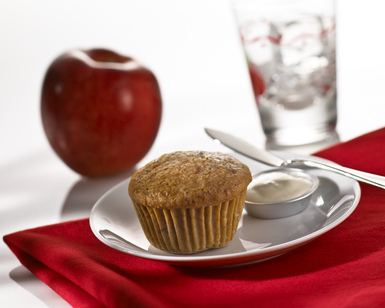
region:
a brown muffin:
[130, 151, 251, 251]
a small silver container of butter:
[246, 166, 318, 219]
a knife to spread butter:
[202, 123, 383, 190]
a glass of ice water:
[234, 3, 342, 148]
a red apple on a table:
[41, 47, 162, 178]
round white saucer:
[86, 153, 362, 263]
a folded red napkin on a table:
[5, 123, 383, 306]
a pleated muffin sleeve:
[130, 190, 253, 255]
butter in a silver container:
[248, 168, 312, 203]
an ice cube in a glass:
[239, 19, 275, 38]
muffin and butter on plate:
[102, 119, 372, 263]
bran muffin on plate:
[142, 161, 246, 250]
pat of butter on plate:
[244, 176, 316, 210]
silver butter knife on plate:
[207, 125, 265, 169]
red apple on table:
[43, 52, 158, 169]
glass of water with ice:
[237, 0, 330, 145]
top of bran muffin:
[146, 153, 225, 203]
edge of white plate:
[146, 247, 170, 266]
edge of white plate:
[235, 243, 263, 267]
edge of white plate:
[294, 227, 315, 246]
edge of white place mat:
[5, 267, 35, 285]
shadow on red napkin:
[198, 267, 249, 286]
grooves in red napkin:
[38, 237, 111, 287]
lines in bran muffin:
[140, 211, 225, 244]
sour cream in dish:
[252, 163, 290, 187]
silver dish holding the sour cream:
[257, 195, 312, 218]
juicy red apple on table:
[41, 49, 153, 148]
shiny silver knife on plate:
[200, 124, 359, 196]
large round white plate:
[74, 158, 353, 277]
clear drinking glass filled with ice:
[221, 3, 343, 148]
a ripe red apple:
[39, 46, 161, 179]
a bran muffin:
[130, 149, 249, 252]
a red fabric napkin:
[4, 124, 384, 306]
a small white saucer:
[91, 141, 359, 265]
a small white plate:
[87, 143, 359, 266]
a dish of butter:
[242, 165, 317, 218]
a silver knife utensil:
[204, 125, 383, 189]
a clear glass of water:
[227, 1, 340, 144]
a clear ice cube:
[239, 18, 276, 64]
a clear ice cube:
[276, 15, 326, 62]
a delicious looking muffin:
[125, 150, 252, 256]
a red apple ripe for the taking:
[39, 45, 165, 182]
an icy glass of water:
[232, 5, 341, 154]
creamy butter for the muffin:
[243, 166, 320, 221]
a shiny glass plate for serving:
[86, 148, 363, 264]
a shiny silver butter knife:
[202, 126, 378, 189]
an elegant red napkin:
[1, 126, 373, 306]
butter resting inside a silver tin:
[243, 171, 309, 201]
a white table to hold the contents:
[3, 5, 377, 223]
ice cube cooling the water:
[281, 91, 314, 109]